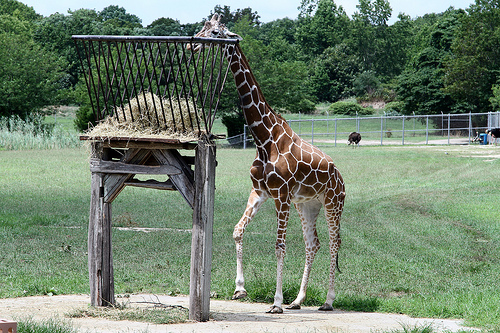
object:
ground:
[46, 244, 427, 308]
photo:
[0, 0, 500, 333]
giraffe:
[186, 12, 346, 313]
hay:
[83, 92, 203, 148]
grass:
[4, 148, 495, 333]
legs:
[232, 186, 346, 300]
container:
[69, 34, 240, 141]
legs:
[86, 140, 218, 322]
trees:
[0, 0, 499, 135]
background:
[3, 2, 499, 161]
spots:
[193, 23, 346, 288]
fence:
[218, 111, 500, 146]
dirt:
[1, 292, 487, 333]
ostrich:
[347, 131, 362, 150]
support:
[78, 134, 218, 322]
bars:
[70, 34, 239, 137]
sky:
[17, 0, 477, 28]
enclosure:
[0, 108, 500, 333]